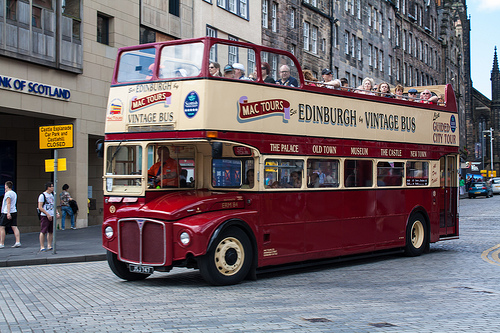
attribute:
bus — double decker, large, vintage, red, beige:
[103, 35, 457, 268]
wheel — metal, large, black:
[188, 219, 259, 285]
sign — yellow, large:
[36, 120, 77, 152]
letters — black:
[42, 126, 67, 146]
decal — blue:
[183, 89, 200, 119]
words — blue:
[1, 73, 73, 106]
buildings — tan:
[0, 2, 499, 230]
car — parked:
[471, 182, 489, 199]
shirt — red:
[146, 160, 184, 188]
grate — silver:
[115, 215, 169, 268]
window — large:
[115, 44, 206, 85]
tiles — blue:
[2, 195, 497, 326]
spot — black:
[306, 311, 332, 326]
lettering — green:
[298, 100, 419, 136]